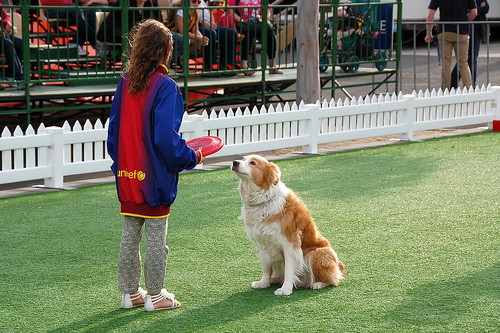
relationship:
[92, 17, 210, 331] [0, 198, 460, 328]
girl standing on grass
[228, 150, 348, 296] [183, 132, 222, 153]
dog looking at frisbee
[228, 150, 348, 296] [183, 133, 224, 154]
dog interested in frisbee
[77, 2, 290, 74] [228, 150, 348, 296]
spectators watching a dog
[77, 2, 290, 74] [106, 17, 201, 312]
spectators watching girl